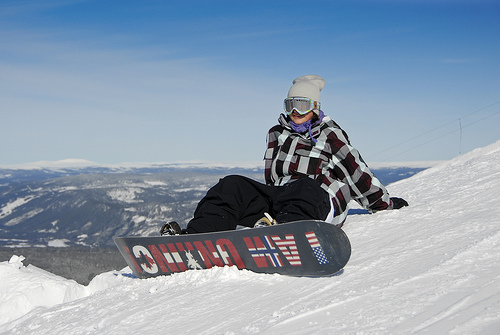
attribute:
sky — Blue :
[70, 31, 182, 75]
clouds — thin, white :
[75, 91, 189, 133]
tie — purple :
[285, 118, 315, 132]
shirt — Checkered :
[242, 111, 413, 225]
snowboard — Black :
[105, 222, 363, 287]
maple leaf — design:
[133, 251, 158, 272]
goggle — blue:
[275, 92, 317, 120]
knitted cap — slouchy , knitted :
[279, 72, 326, 116]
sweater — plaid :
[261, 113, 393, 227]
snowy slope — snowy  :
[28, 137, 496, 330]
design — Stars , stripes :
[304, 227, 343, 272]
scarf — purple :
[274, 113, 335, 140]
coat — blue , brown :
[263, 117, 406, 232]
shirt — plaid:
[260, 117, 387, 225]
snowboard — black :
[108, 216, 354, 281]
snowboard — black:
[234, 227, 346, 282]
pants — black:
[184, 177, 329, 233]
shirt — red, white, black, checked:
[264, 114, 392, 226]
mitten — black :
[389, 196, 408, 209]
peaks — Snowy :
[7, 146, 309, 240]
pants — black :
[183, 170, 333, 234]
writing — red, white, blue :
[124, 240, 336, 271]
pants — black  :
[168, 167, 333, 245]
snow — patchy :
[1, 156, 439, 245]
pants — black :
[173, 171, 335, 236]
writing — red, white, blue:
[112, 234, 332, 274]